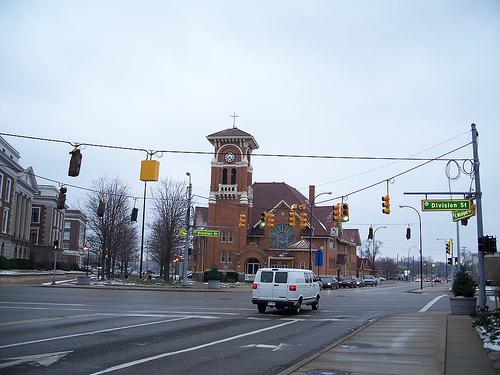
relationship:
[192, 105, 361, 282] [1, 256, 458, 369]
church on street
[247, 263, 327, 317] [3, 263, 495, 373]
van on street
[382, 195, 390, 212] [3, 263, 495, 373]
traffic light above street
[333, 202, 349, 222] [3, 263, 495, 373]
traffic light above street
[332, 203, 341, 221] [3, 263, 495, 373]
traffic light above street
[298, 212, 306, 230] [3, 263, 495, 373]
traffic light above street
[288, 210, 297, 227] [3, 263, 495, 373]
traffic light above street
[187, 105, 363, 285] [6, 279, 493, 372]
church beside street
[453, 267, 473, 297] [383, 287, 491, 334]
tree on corner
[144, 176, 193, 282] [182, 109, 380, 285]
tree beside church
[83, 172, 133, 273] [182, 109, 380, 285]
tree beside church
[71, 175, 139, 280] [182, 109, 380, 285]
tree beside church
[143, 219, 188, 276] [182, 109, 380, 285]
tree beside church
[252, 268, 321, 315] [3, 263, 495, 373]
van down street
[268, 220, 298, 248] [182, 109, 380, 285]
window on church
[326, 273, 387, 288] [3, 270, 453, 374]
traffic on street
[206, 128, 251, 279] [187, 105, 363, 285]
clock tower on church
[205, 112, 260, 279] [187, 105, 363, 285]
clock tower on church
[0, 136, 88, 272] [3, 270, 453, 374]
building beside street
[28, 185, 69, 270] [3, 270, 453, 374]
building beside street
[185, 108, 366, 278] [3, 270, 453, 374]
building beside street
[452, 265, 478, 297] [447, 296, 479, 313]
tree planted in a pot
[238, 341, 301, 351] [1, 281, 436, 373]
arrow on road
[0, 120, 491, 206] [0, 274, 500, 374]
cable across pavement